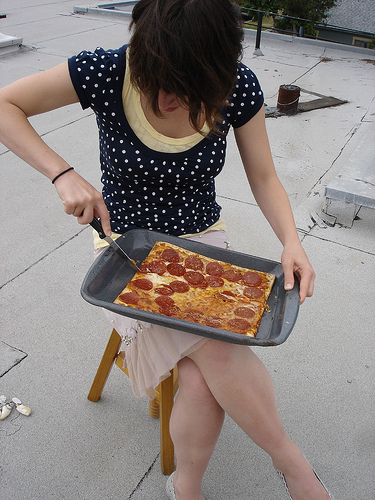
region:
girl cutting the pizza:
[43, 3, 319, 498]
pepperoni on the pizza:
[163, 272, 189, 299]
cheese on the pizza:
[157, 276, 162, 284]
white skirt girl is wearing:
[131, 338, 171, 374]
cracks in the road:
[315, 211, 346, 251]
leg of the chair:
[82, 358, 115, 413]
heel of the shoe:
[160, 474, 178, 498]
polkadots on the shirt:
[149, 164, 200, 195]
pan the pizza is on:
[268, 318, 288, 344]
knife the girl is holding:
[105, 239, 143, 277]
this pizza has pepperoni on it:
[177, 265, 208, 322]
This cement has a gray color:
[319, 380, 336, 414]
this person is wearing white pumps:
[160, 467, 180, 498]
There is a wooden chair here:
[96, 344, 122, 414]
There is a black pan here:
[271, 325, 283, 347]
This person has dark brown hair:
[169, 38, 199, 94]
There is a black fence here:
[285, 20, 297, 45]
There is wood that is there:
[94, 351, 115, 395]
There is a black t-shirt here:
[95, 51, 104, 75]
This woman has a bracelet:
[52, 161, 94, 217]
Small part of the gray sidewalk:
[37, 292, 58, 311]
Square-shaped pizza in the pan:
[113, 237, 277, 336]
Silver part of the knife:
[109, 240, 141, 269]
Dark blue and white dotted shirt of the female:
[135, 163, 195, 211]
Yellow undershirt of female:
[145, 130, 158, 145]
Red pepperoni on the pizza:
[184, 268, 209, 288]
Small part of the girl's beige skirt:
[135, 336, 176, 364]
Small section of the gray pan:
[98, 263, 118, 288]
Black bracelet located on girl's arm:
[49, 162, 74, 183]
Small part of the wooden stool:
[93, 367, 106, 397]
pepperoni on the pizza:
[181, 266, 207, 284]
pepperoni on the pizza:
[155, 284, 168, 296]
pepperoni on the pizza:
[244, 286, 261, 297]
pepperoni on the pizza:
[165, 305, 176, 312]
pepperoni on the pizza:
[234, 306, 250, 317]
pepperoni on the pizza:
[204, 262, 216, 274]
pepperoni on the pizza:
[187, 258, 199, 269]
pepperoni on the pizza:
[242, 271, 261, 289]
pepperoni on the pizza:
[167, 249, 179, 263]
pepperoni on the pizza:
[163, 249, 177, 258]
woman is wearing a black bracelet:
[41, 156, 79, 194]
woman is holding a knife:
[76, 203, 145, 276]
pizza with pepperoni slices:
[111, 227, 272, 337]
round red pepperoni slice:
[163, 241, 182, 265]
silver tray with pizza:
[77, 220, 302, 348]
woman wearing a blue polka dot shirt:
[55, 42, 267, 241]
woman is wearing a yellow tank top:
[108, 46, 223, 164]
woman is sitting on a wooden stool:
[70, 322, 176, 486]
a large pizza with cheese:
[121, 234, 274, 339]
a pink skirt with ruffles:
[98, 322, 191, 402]